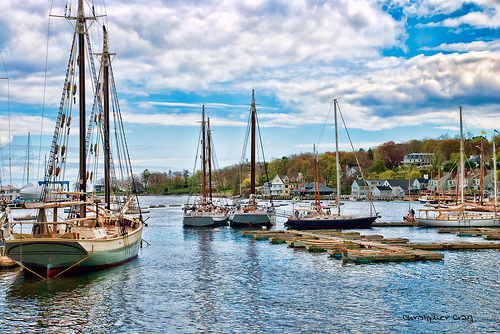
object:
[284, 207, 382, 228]
boat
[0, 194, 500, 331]
water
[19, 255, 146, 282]
red bottom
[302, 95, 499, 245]
boats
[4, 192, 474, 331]
harbor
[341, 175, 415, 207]
buildings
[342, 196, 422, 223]
shore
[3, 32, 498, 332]
lake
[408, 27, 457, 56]
sky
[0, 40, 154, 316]
sailboat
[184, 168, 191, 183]
tree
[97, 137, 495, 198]
hill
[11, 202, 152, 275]
boat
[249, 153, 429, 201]
tree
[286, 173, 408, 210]
houses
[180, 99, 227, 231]
boat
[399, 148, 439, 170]
house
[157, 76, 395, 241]
boats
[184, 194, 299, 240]
boats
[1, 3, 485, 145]
clouds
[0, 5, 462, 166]
sky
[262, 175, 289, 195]
house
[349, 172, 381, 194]
house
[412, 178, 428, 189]
house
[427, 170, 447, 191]
house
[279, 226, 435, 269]
dock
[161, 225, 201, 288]
lake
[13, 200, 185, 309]
water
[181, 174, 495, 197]
shore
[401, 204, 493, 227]
boat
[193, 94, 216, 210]
mast